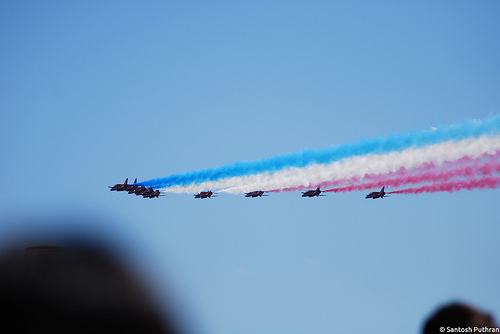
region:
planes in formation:
[110, 165, 415, 224]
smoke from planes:
[400, 123, 466, 217]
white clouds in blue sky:
[46, 32, 88, 76]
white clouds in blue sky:
[81, 97, 136, 139]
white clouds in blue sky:
[224, 241, 283, 272]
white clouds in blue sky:
[332, 245, 370, 282]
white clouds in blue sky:
[231, 211, 281, 294]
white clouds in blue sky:
[246, 30, 283, 65]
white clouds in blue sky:
[306, 13, 363, 68]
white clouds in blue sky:
[174, 63, 254, 130]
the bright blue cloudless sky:
[0, 5, 499, 332]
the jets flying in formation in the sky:
[106, 173, 388, 203]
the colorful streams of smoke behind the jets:
[138, 118, 498, 195]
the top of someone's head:
[421, 298, 499, 330]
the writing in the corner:
[439, 324, 499, 332]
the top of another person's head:
[9, 251, 176, 332]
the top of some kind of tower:
[21, 238, 61, 253]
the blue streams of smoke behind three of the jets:
[141, 112, 495, 187]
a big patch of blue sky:
[12, 8, 246, 140]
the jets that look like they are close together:
[104, 177, 163, 199]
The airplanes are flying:
[61, 51, 498, 253]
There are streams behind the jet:
[113, 108, 498, 230]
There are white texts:
[419, 301, 498, 332]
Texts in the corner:
[429, 313, 499, 330]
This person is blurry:
[2, 217, 181, 332]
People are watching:
[0, 192, 497, 332]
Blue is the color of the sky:
[55, 15, 390, 116]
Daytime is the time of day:
[15, 15, 386, 130]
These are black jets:
[73, 156, 408, 232]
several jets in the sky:
[106, 178, 404, 202]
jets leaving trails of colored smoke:
[101, 110, 498, 207]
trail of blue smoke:
[135, 112, 499, 191]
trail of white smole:
[161, 138, 498, 197]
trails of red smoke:
[266, 145, 498, 198]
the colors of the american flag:
[121, 109, 496, 194]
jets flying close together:
[106, 174, 167, 201]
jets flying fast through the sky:
[105, 174, 395, 205]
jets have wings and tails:
[103, 175, 391, 205]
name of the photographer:
[436, 323, 498, 332]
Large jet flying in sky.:
[358, 188, 422, 218]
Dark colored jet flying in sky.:
[295, 182, 345, 210]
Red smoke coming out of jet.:
[403, 178, 452, 204]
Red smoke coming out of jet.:
[326, 182, 356, 202]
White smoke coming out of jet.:
[266, 180, 290, 187]